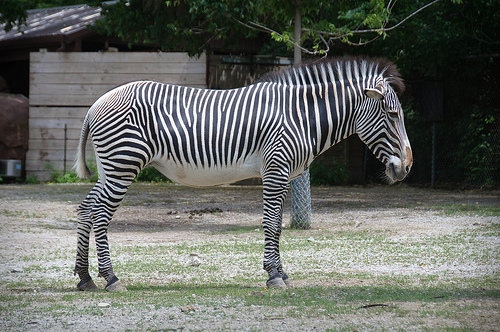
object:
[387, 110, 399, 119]
eye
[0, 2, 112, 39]
roof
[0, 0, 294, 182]
building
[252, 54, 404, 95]
hair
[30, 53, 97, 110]
wall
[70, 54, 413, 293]
zebra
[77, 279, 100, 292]
hooves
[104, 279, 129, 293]
hooves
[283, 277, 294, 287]
hooves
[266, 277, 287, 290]
hooves